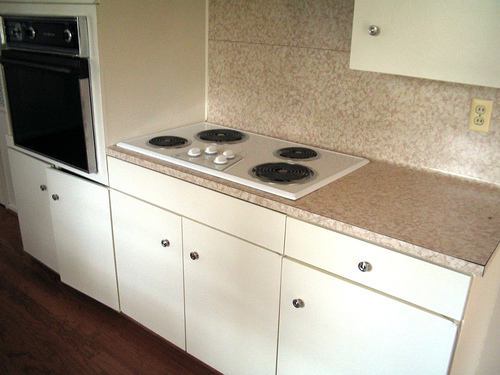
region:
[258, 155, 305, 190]
eye on stove top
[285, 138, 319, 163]
eye on stove top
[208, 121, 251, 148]
eye on stove top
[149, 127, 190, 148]
eye on stove top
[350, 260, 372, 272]
knob on cabinet drawer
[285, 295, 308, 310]
knob on cabinet door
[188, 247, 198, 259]
knob on cabinet door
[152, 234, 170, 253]
knob on cabinet door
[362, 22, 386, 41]
knob on cabinet door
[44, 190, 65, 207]
knob on cabinet door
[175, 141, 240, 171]
Four white dials on between burners.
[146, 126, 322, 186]
Four black burners on a white stove top.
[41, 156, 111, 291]
Open white cabinet below oven.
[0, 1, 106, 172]
Black oven above white cabinets.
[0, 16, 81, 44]
Three black and chrome dials on oven.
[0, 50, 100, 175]
Black and chrome oven doors.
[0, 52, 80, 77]
Black and chrome oven handle.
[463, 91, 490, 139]
Beige wall plugs in below wall cabinet.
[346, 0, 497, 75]
Single white cabinet above plug.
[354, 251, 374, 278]
Single knob to white cabinet drawer.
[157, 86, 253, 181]
the stove is white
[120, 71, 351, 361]
the stove is white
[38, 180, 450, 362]
cabinets in a kitchen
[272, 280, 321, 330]
cabinets have round silver knobs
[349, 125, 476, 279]
tan counter top and backsplash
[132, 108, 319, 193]
electric cook top with four burners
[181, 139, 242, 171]
white knobs control the burners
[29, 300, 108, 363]
floor is dark wood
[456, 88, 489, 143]
electric outlet under cabinet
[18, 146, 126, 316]
one cabinet door is not closed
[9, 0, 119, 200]
oven mounted in wall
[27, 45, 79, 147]
oven has black front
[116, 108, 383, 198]
white counter top stove with white knobs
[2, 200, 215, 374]
old style hardwood floors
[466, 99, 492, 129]
outlet under the white cabinet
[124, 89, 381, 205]
counter stove (white)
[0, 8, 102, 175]
dish washer (silver and black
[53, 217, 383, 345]
white cabinets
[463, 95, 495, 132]
white plug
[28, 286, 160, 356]
a wooden floor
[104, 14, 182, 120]
a tan wall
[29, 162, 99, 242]
kinda of a white cabinet open